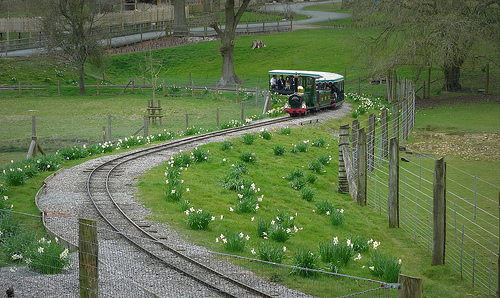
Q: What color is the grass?
A: Green.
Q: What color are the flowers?
A: White.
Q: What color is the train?
A: Red and green.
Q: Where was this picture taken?
A: The railway.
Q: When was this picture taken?
A: Daytime.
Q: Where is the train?
A: The train tracks.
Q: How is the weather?
A: Clear.